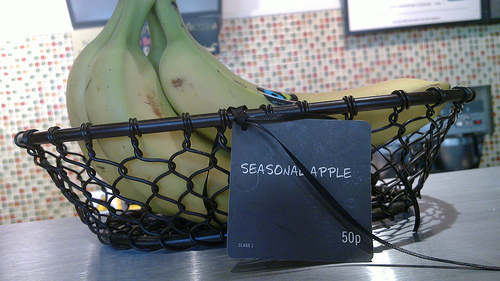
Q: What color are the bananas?
A: Yellow.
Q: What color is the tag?
A: Black.